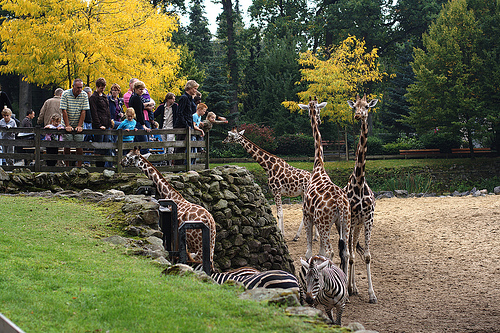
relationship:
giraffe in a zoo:
[121, 145, 217, 267] [1, 127, 499, 332]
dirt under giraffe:
[267, 193, 499, 331] [121, 145, 217, 263]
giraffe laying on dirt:
[181, 244, 261, 276] [267, 193, 499, 331]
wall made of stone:
[1, 166, 295, 276] [223, 187, 237, 201]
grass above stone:
[2, 195, 347, 331] [223, 187, 237, 201]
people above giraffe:
[1, 79, 228, 166] [121, 145, 217, 263]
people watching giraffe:
[1, 79, 228, 166] [121, 145, 217, 263]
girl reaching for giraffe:
[202, 112, 226, 134] [221, 125, 312, 245]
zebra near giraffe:
[172, 257, 300, 297] [181, 244, 261, 276]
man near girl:
[193, 97, 226, 121] [202, 112, 226, 134]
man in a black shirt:
[89, 79, 117, 166] [89, 90, 114, 130]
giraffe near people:
[221, 125, 312, 245] [1, 79, 228, 166]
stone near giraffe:
[223, 187, 237, 201] [121, 145, 217, 267]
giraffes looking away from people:
[298, 96, 379, 305] [1, 79, 228, 166]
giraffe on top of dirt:
[121, 145, 217, 263] [267, 193, 499, 331]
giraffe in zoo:
[121, 145, 217, 263] [1, 127, 499, 332]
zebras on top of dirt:
[171, 257, 346, 327] [267, 193, 499, 331]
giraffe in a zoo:
[121, 145, 217, 263] [1, 127, 499, 332]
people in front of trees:
[1, 79, 228, 166] [1, 1, 191, 108]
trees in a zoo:
[1, 1, 191, 108] [1, 127, 499, 332]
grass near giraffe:
[2, 195, 347, 331] [121, 145, 217, 263]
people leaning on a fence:
[1, 79, 228, 166] [1, 126, 211, 172]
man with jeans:
[89, 79, 117, 166] [92, 126, 113, 167]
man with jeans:
[129, 82, 151, 158] [134, 124, 150, 155]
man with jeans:
[176, 79, 201, 166] [175, 132, 187, 167]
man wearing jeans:
[89, 79, 117, 166] [92, 126, 113, 167]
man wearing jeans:
[129, 82, 151, 158] [134, 124, 150, 155]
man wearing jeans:
[176, 79, 201, 166] [175, 132, 187, 167]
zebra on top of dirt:
[172, 257, 300, 297] [267, 193, 499, 331]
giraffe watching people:
[121, 145, 217, 267] [1, 79, 228, 166]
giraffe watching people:
[221, 125, 312, 245] [1, 79, 228, 166]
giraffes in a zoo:
[298, 96, 379, 305] [1, 127, 499, 332]